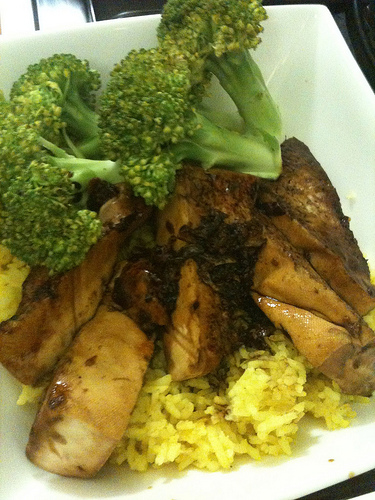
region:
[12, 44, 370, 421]
the food on the plate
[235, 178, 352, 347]
the chicken on the plate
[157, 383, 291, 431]
the rice on the plate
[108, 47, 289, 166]
the broccoli on the plate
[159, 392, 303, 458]
the rice is yellow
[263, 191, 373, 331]
the chicken is glistening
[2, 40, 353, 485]
the plate is white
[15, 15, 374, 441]
the plate is square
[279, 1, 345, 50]
the corner of the plate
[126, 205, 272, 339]
sauce on the chicken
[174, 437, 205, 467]
part of some rice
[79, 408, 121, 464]
edge of a potato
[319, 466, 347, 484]
edge of a dish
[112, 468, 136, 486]
part of a shade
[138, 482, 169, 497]
edge of a shade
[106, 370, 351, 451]
YELLOW RICE UNDER MEAT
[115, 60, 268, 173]
broccoli steamed as side dish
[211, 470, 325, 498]
food is on white plate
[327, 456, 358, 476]
dribbles of sauce on plate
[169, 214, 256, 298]
black sauce poured on meat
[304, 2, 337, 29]
corner of white plate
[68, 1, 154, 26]
plate is sitting on sink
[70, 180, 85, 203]
black spots on broccoli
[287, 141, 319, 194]
dark area of meat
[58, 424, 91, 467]
light area of meat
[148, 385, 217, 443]
yellow peices of rice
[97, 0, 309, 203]
piece of broccoli with 2 stalks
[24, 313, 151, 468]
slice of grilled chicken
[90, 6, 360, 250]
stalks of broccoli on grilled chicken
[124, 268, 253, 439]
grilled chicken on top of fried rice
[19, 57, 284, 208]
green pieces of broccoli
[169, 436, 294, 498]
yellow rice on a white plate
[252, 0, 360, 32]
corner edge of white glass plate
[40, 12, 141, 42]
top edge of white plate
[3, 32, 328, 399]
chicken, broccoli and rice on a white plate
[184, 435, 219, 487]
part of some rice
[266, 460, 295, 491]
part of a plate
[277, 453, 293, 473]
part of some rticw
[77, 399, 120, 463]
part of a cassava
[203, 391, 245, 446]
part of some rice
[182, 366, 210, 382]
part of a potato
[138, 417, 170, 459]
part of some rice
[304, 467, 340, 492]
edge of a dish